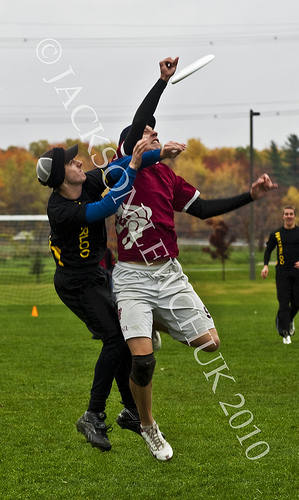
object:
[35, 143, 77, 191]
band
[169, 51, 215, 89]
frisbee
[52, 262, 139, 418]
pants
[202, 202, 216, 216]
black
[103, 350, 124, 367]
black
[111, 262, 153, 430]
leg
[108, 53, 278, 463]
man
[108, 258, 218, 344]
shorts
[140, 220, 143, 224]
white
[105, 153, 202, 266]
shirt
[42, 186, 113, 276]
shirt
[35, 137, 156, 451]
man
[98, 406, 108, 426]
black cleats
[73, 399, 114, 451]
foot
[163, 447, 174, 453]
white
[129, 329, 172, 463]
foot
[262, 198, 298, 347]
man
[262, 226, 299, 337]
black cloths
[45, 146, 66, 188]
sweatband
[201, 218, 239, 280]
tree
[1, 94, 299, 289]
background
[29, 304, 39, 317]
cone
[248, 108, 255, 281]
pole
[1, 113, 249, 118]
electric line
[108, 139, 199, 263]
color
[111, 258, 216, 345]
color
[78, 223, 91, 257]
color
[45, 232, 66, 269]
color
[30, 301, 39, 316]
color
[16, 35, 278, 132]
light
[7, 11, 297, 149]
sky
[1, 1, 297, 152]
air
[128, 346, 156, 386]
pad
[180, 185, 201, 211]
trim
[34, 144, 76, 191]
cap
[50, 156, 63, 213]
warmer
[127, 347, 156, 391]
brace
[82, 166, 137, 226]
sleeves